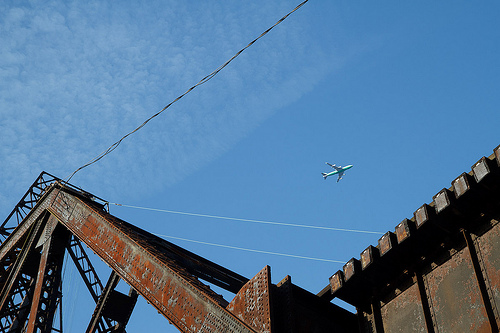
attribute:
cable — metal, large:
[80, 59, 220, 197]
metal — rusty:
[28, 176, 352, 331]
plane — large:
[309, 150, 356, 182]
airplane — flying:
[319, 161, 353, 183]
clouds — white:
[206, 98, 259, 145]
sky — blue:
[284, 117, 424, 157]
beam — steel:
[0, 172, 352, 321]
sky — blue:
[1, 2, 492, 289]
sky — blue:
[0, 0, 492, 331]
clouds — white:
[3, 1, 403, 208]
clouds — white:
[33, 26, 143, 105]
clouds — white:
[62, 93, 121, 131]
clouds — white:
[66, 27, 279, 127]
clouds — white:
[17, 9, 291, 134]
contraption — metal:
[2, 162, 418, 331]